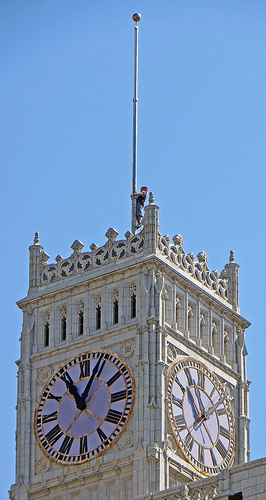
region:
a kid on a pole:
[125, 8, 150, 236]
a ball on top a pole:
[129, 9, 143, 47]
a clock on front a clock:
[27, 347, 139, 472]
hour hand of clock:
[63, 375, 85, 414]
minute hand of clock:
[77, 351, 109, 408]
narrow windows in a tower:
[28, 285, 140, 348]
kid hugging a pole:
[125, 179, 153, 233]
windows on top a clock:
[155, 281, 246, 480]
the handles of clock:
[188, 376, 227, 433]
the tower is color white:
[2, 186, 264, 498]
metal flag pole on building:
[119, 14, 143, 186]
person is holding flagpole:
[125, 189, 154, 233]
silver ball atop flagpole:
[129, 15, 143, 26]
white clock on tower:
[167, 366, 235, 466]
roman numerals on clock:
[174, 364, 231, 463]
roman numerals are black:
[171, 372, 231, 454]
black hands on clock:
[184, 367, 227, 447]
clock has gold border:
[165, 362, 240, 469]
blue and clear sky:
[185, 179, 243, 236]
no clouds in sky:
[184, 179, 236, 230]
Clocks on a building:
[29, 346, 238, 476]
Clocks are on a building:
[29, 346, 241, 477]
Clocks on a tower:
[30, 349, 243, 475]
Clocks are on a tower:
[31, 346, 235, 480]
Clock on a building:
[33, 346, 139, 467]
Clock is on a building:
[28, 348, 137, 466]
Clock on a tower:
[32, 350, 137, 465]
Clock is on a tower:
[35, 348, 138, 466]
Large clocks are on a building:
[32, 345, 238, 478]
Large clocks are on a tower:
[28, 346, 239, 479]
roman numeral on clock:
[76, 359, 90, 380]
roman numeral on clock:
[96, 360, 107, 378]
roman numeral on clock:
[105, 371, 120, 388]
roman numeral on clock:
[108, 389, 127, 401]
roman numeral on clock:
[103, 405, 121, 424]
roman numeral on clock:
[96, 428, 107, 442]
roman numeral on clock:
[78, 436, 88, 453]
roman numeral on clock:
[58, 434, 74, 454]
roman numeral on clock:
[43, 423, 60, 447]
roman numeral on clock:
[41, 409, 58, 424]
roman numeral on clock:
[96, 427, 106, 443]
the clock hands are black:
[64, 353, 104, 409]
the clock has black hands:
[33, 349, 134, 465]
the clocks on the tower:
[0, 190, 265, 498]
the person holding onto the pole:
[130, 13, 147, 234]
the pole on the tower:
[0, 13, 265, 499]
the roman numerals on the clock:
[33, 348, 135, 465]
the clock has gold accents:
[34, 347, 135, 466]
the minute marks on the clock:
[33, 350, 135, 465]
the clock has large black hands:
[33, 348, 134, 465]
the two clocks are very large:
[33, 349, 236, 475]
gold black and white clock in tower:
[27, 346, 144, 457]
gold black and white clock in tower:
[165, 350, 234, 467]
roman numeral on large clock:
[100, 406, 127, 426]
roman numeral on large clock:
[92, 423, 109, 442]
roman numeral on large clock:
[76, 432, 93, 453]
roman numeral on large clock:
[54, 432, 76, 458]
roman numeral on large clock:
[102, 361, 121, 387]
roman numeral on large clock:
[167, 412, 186, 434]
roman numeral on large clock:
[178, 430, 198, 452]